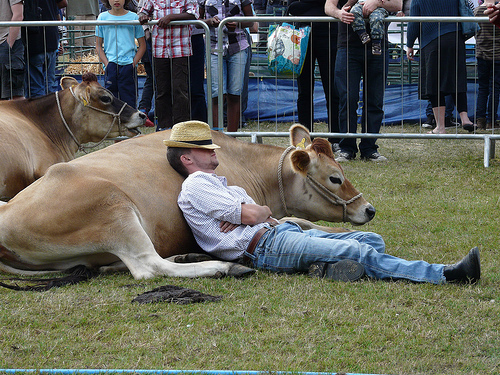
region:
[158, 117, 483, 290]
Man lying on a cow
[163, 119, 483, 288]
Man wearing a light blue shirt and jeans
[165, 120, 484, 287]
Man wearing black shoes and a straw hat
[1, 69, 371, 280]
Two cows lying on the grass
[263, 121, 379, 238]
Brown cow wearing a halter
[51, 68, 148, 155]
Brown cow wearing a halter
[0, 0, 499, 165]
People behind metal barriers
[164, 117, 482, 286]
Man sitting on ground and leaning against cow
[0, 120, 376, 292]
Light brown cow lying on ground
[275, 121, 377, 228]
Head of cow wearing rope halter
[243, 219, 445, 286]
Blue jeans with brown leather belt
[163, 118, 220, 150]
Tan straw fedora with black band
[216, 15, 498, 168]
Metal fence or gate panel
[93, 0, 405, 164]
Group of people standing at fence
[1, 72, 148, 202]
Reclining brown cow with open mouth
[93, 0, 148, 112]
Young girl or boy wearing light blue shirt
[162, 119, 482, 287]
Man with hat over eyes napping while leaning against cow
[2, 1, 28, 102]
person standing behind fence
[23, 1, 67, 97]
person standing behind fence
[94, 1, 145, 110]
person standing behind fence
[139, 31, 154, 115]
person standing behind fence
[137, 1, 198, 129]
person standing behind fence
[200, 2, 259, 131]
person standing behind fence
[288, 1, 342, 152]
person standing behind fence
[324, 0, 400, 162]
person standing behind fence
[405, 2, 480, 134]
person standing behind fence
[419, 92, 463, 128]
person standing behind fence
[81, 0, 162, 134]
boy wearing blue shirt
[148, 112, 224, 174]
man wearing hat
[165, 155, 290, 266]
man wearing plaid shirt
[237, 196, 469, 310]
man wearing blue jeans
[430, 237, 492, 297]
man wearing black boots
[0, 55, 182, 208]
brown cow laying on grass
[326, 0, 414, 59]
boy sitting on fence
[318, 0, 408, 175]
man holding boy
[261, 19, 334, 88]
man holding blue bag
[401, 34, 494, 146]
lady wearing black skirt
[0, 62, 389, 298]
Two cows laying on grass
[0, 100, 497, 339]
man laying on cow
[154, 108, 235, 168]
man wearing a hat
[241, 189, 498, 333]
man wearing jeans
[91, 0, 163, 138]
boy wearing a blue shirt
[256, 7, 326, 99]
man holding bag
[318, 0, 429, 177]
man holding child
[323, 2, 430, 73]
child sitting on fence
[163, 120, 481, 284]
man is laying on cows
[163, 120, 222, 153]
hat is made of straw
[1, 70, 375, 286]
brown cows on ground